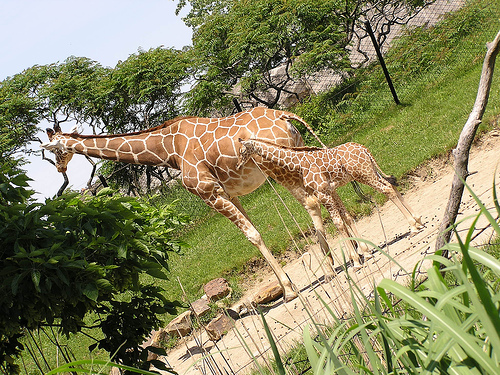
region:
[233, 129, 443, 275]
baby giraffe next to mom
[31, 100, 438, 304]
two giraffes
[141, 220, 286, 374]
rocks below the giraffes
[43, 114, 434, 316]
mom giraffe is in front of the baby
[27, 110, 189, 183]
giraffe has a long neck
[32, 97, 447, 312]
giraffes are brown and white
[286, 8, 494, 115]
metal fence along the trees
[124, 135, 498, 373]
path in the grass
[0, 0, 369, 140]
trees on the sides of the giraffes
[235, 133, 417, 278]
this is a baby giraffe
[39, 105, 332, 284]
this is a giraffe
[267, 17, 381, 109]
this is a branch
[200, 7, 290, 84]
this is a branch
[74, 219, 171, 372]
this is a branch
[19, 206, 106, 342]
this is a branch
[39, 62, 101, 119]
this is a branch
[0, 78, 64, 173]
this is a branch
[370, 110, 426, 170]
the grass is very lush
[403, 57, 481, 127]
the grass is very lush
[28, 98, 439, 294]
two giraffes on the dirt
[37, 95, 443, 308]
a baby giraffe next to an adult giraffe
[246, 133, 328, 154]
hair running along the neck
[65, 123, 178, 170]
brown spots along the neck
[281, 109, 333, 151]
tail hanging off the behind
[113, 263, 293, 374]
boulders on the ground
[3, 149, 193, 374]
green leaves on the tree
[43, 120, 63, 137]
two horns on the top of the head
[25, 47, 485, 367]
The giraffes are in an enclosure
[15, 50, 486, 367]
The giraffes are in a zoo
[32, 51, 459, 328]
A giraffe is standing with her baby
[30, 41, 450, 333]
A giraffe is protecting her young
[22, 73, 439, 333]
The giraffes are waiting to be fed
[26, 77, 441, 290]
The giraffes are close to some bushes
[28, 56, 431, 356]
Some giraffes are close to the rocks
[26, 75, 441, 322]
The giraffes are out in the daytime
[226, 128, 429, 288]
young orange and white giraffe standing near adult giraffe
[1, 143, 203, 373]
green tree near giraffes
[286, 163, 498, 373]
tall thick green grass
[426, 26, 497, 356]
light gray wooden tree branch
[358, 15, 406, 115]
black fence post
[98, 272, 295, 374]
light brown gray and yellow rocks on the ground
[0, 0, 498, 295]
metal chain-link fence around giraffe enclosure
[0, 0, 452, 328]
green trees near giraffe enclosure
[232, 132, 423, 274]
Smallest of the giraffes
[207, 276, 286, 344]
Rocks by giraffes feet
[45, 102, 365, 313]
The mother giraffe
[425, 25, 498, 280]
Long stick by tall grass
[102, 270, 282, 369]
Large rocks near giraffes feet.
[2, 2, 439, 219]
Tall trees behind fence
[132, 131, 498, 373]
Patch of dirt in the grass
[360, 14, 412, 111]
Black post for fencing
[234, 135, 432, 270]
Baby giraffe near mother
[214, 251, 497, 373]
Tall grass near long stick